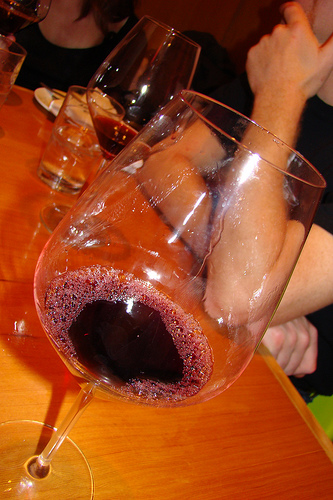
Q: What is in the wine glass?
A: Purple colored wine.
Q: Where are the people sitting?
A: At a brown table.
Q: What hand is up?
A: The man's.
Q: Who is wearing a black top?
A: The woman.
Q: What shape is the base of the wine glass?
A: Circle.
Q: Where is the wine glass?
A: On the table.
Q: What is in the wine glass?
A: Wine.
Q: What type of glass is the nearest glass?
A: Wine glass.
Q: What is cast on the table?
A: Shadows.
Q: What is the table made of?
A: Wood.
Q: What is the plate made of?
A: Porcelain.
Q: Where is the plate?
A: The far end of the table.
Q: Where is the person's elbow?
A: On the edge of the table.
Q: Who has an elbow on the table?
A: The person on the right.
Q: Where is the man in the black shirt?
A: On the right.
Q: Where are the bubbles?
A: In the red wine glass.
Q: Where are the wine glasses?
A: On a table.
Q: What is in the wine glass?
A: Wine.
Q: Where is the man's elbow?
A: On the table.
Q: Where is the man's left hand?
A: By his face.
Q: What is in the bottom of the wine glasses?
A: Wine.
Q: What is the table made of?
A: Wood.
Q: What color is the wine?
A: Red.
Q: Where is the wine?
A: In a glass.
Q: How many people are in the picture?
A: Two.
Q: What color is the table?
A: Brown.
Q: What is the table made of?
A: Wood.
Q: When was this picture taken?
A: At a mealtime.